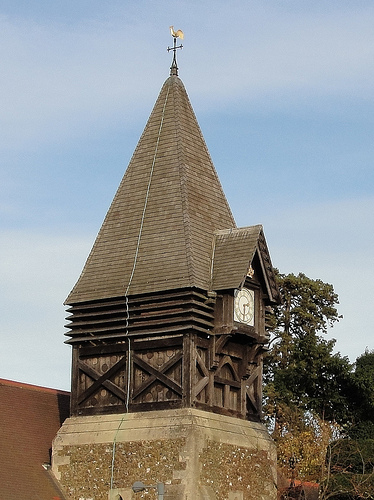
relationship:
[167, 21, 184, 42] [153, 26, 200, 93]
rooster on top of tower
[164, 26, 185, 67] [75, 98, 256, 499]
cross on top of building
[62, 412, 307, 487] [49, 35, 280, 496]
base on spire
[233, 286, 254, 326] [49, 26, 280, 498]
clock on building